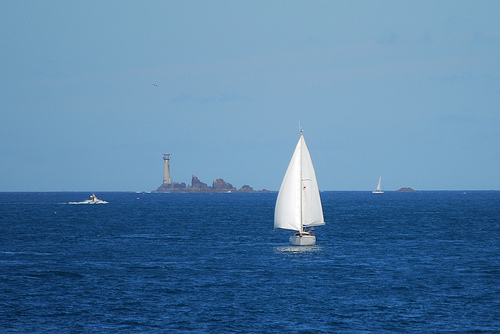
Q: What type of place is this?
A: It is a sea.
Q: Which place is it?
A: It is a sea.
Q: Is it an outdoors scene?
A: Yes, it is outdoors.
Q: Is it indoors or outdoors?
A: It is outdoors.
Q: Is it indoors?
A: No, it is outdoors.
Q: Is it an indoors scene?
A: No, it is outdoors.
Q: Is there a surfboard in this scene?
A: No, there are no surfboards.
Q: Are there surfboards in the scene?
A: No, there are no surfboards.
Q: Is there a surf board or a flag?
A: No, there are no surfboards or flags.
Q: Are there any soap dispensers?
A: No, there are no soap dispensers.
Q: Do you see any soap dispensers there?
A: No, there are no soap dispensers.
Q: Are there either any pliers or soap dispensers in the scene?
A: No, there are no soap dispensers or pliers.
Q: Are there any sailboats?
A: Yes, there is a sailboat.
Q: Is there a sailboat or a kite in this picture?
A: Yes, there is a sailboat.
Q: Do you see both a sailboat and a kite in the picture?
A: No, there is a sailboat but no kites.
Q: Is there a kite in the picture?
A: No, there are no kites.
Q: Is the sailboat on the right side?
A: Yes, the sailboat is on the right of the image.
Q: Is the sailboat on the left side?
A: No, the sailboat is on the right of the image.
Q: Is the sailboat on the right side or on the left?
A: The sailboat is on the right of the image.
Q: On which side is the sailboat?
A: The sailboat is on the right of the image.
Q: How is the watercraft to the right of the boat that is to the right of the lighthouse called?
A: The watercraft is a sailboat.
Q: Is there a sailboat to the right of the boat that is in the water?
A: Yes, there is a sailboat to the right of the boat.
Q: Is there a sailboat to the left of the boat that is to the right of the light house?
A: No, the sailboat is to the right of the boat.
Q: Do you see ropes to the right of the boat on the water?
A: No, there is a sailboat to the right of the boat.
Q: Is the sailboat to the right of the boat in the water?
A: Yes, the sailboat is to the right of the boat.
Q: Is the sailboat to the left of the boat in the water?
A: No, the sailboat is to the right of the boat.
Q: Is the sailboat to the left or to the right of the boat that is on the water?
A: The sailboat is to the right of the boat.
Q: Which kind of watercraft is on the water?
A: The watercraft is a sailboat.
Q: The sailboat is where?
A: The sailboat is on the water.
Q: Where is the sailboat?
A: The sailboat is on the water.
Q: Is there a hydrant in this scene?
A: No, there are no fire hydrants.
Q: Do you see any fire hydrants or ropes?
A: No, there are no fire hydrants or ropes.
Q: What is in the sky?
A: The clouds are in the sky.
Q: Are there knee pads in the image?
A: No, there are no knee pads.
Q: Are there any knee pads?
A: No, there are no knee pads.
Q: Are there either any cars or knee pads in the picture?
A: No, there are no knee pads or cars.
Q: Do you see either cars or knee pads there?
A: No, there are no knee pads or cars.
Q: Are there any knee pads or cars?
A: No, there are no knee pads or cars.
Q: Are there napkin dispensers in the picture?
A: No, there are no napkin dispensers.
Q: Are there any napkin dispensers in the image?
A: No, there are no napkin dispensers.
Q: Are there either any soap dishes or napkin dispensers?
A: No, there are no napkin dispensers or soap dishes.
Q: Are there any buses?
A: No, there are no buses.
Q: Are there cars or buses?
A: No, there are no buses or cars.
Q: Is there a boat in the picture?
A: Yes, there is a boat.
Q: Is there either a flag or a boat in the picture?
A: Yes, there is a boat.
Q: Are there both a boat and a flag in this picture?
A: No, there is a boat but no flags.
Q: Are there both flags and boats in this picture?
A: No, there is a boat but no flags.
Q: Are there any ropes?
A: No, there are no ropes.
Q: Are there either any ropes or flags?
A: No, there are no ropes or flags.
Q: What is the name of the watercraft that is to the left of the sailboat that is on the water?
A: The watercraft is a boat.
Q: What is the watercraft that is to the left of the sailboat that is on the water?
A: The watercraft is a boat.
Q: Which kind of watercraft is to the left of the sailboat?
A: The watercraft is a boat.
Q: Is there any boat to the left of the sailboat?
A: Yes, there is a boat to the left of the sailboat.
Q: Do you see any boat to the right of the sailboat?
A: No, the boat is to the left of the sailboat.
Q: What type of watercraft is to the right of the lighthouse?
A: The watercraft is a boat.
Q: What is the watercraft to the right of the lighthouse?
A: The watercraft is a boat.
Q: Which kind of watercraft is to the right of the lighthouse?
A: The watercraft is a boat.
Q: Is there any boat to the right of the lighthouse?
A: Yes, there is a boat to the right of the lighthouse.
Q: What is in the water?
A: The boat is in the water.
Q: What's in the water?
A: The boat is in the water.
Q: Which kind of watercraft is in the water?
A: The watercraft is a boat.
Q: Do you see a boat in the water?
A: Yes, there is a boat in the water.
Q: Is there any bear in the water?
A: No, there is a boat in the water.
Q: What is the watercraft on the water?
A: The watercraft is a boat.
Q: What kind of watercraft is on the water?
A: The watercraft is a boat.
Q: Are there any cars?
A: No, there are no cars.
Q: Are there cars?
A: No, there are no cars.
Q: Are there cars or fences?
A: No, there are no cars or fences.